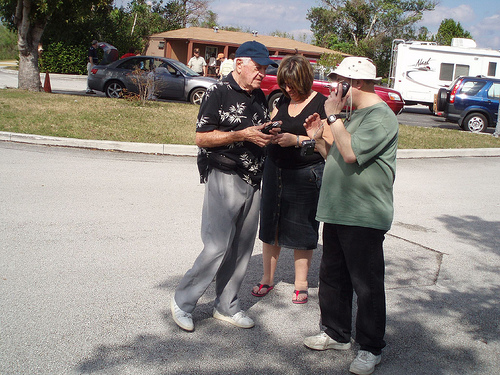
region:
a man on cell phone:
[313, 44, 408, 149]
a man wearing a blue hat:
[206, 18, 275, 310]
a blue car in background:
[439, 68, 494, 128]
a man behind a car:
[81, 35, 111, 94]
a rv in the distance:
[392, 20, 498, 119]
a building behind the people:
[126, 13, 385, 105]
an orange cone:
[38, 63, 55, 109]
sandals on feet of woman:
[251, 265, 330, 312]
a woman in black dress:
[268, 37, 325, 280]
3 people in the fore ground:
[186, 26, 444, 338]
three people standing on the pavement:
[195, 35, 415, 358]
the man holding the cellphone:
[320, 55, 411, 358]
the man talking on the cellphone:
[315, 45, 412, 359]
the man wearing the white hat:
[319, 56, 403, 90]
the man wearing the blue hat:
[224, 24, 280, 74]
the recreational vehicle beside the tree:
[377, 34, 494, 95]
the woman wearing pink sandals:
[257, 125, 325, 315]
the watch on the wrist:
[317, 104, 357, 131]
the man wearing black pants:
[302, 191, 397, 352]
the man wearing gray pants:
[172, 174, 270, 324]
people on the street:
[165, 38, 420, 183]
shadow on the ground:
[100, 306, 171, 362]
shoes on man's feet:
[155, 272, 255, 347]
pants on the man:
[295, 217, 405, 338]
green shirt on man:
[307, 111, 407, 231]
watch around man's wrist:
[320, 102, 347, 128]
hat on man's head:
[323, 53, 384, 90]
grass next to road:
[57, 97, 132, 138]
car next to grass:
[91, 40, 209, 107]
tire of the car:
[457, 101, 494, 140]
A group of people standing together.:
[171, 39, 396, 374]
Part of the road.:
[65, 220, 142, 290]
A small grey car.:
[84, 54, 219, 107]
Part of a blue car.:
[439, 74, 499, 133]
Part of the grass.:
[61, 108, 131, 126]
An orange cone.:
[42, 69, 54, 94]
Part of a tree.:
[8, 10, 64, 37]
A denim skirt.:
[259, 158, 324, 251]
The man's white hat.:
[327, 55, 384, 85]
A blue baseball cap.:
[233, 40, 278, 70]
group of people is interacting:
[169, 40, 399, 374]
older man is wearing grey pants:
[172, 162, 261, 317]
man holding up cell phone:
[336, 81, 349, 99]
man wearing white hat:
[326, 55, 382, 81]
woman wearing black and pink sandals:
[250, 282, 310, 304]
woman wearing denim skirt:
[257, 156, 325, 251]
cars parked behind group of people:
[85, 55, 499, 133]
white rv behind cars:
[387, 36, 499, 113]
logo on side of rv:
[400, 58, 439, 90]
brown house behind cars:
[143, 25, 351, 79]